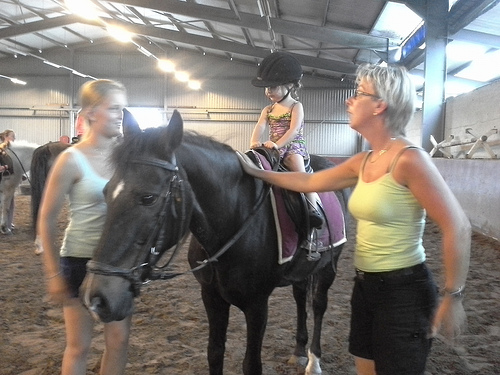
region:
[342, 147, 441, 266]
The woman is wearing a yellow shirt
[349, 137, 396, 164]
The woman is wearing a chain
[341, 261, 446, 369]
The woman is wearing a black pant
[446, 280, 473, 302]
The woman is wearing a watch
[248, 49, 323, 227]
young girl on horse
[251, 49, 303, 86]
a black riding helmet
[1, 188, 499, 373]
dirt-covered ground in the barn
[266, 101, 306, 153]
colorful dress on the girl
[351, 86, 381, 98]
glasses on the woman's face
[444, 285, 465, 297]
a watch on the woman's wrist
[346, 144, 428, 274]
a yellow shirt on the woman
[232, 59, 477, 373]
woman in yellow shirt petting horse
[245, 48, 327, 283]
child sitting on horse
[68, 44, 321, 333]
little girl on horse wearing helmet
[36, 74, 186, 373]
young girl standing by horse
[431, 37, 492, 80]
sunlight shinning thru sky lights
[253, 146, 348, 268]
purple blanket on black horse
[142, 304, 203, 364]
horse tracks in the sand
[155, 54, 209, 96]
lights on above riding stable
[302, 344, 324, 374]
white spot on horses foot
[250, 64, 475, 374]
woman in black shorts talking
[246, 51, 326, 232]
a little girl on a horse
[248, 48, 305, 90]
a childs safety helmet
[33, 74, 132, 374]
a girl near a horse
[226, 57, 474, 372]
a woman in a yellow top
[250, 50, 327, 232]
a little girl in a helmet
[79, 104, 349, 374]
a horse with a red blanket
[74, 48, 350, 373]
a horse with a child on it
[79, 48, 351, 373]
a small child riding a horse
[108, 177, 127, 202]
a white diamond ona horse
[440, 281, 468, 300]
a woman wrist watch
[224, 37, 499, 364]
lady holding horse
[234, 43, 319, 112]
little girl wearing black helmet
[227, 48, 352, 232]
little girl on horse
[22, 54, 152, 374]
girl standing next to horse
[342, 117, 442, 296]
lady wearing green tank top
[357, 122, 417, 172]
lady wearing necklace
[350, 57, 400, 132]
lady wearing glasses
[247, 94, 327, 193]
little girl wearing floral dress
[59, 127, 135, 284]
girl wearing white tank top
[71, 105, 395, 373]
black horse in barn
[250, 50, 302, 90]
small black riding helmet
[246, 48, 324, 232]
girl riding a horse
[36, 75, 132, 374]
girl in a white shirt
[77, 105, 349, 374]
black horse with white diamond on head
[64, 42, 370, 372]
little girl on horse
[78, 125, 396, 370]
black horse in stable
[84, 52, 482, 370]
lady touching horse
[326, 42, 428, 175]
lady wearing glasses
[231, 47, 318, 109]
little girl wearing black hat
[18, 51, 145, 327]
girl wearing white shirt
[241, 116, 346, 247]
black saddles on horse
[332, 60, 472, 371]
woman standing next to horse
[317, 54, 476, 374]
woman standing on dirt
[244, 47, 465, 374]
woman standing with child